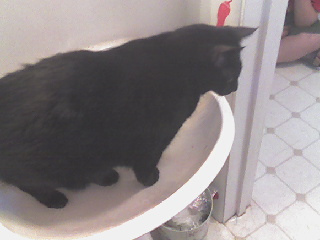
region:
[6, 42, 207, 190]
black cat on white sink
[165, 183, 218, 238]
metal trash recepticle under sink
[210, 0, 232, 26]
red pepper behind cat's head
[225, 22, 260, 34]
black pointy ear of cat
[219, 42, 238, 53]
black pointy ear of cat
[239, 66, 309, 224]
White and tan tile floor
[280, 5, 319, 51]
tan and green chair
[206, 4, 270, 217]
white wall divider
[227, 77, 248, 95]
nose of black cat on sink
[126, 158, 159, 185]
right front paw of cat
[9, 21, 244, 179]
the cat is black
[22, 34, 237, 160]
large black furry cat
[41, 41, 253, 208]
cat standing in sink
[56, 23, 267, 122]
cat looking down at floor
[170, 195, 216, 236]
trash can beneath sink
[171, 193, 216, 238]
trash can contains plastic bag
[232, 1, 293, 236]
grey door frame by sink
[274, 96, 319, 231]
white and pink linoleum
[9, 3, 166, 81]
white wall behind sink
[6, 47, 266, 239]
sink is oval shaped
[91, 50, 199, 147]
cat is overweight with long fur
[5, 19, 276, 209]
The cat is black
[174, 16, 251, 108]
the cat is looking to the right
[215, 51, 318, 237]
Linoleum flooring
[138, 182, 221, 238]
A trash can under the cat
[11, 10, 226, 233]
The cat is on something white.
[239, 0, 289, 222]
A doorway to the other room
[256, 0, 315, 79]
Somebody sitting on the floor in the other room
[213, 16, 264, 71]
The cats ears are at attention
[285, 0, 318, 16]
Person in the other room with a red top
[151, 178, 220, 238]
There's garbage in the can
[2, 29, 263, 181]
black cat in the photo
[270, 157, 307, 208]
tile below the cat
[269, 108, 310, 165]
squares on the tile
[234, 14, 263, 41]
ear of the cat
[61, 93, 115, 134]
fur of the cat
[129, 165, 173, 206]
paw of the cat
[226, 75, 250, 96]
nose of the cat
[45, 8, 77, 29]
wall next to the cat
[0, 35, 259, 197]
cat looking at the ground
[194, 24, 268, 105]
head of the cat